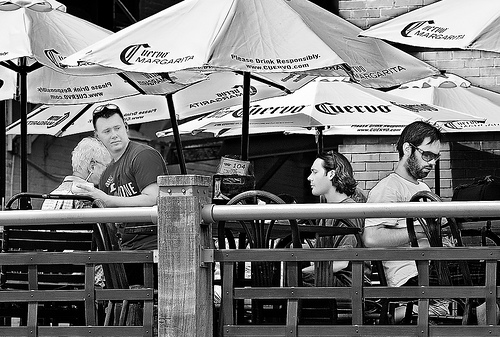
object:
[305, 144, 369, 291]
person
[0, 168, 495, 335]
patio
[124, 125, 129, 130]
earbuds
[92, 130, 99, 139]
ears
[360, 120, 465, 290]
man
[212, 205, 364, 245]
table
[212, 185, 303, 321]
chair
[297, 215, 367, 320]
chair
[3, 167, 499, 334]
fence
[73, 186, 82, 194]
glass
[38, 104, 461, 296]
people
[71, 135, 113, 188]
head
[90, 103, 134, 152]
head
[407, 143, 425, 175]
beard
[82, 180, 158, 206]
arm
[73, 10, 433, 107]
umbrella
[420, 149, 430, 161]
eye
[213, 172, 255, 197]
box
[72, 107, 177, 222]
person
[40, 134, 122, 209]
person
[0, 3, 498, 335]
cafe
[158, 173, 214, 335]
pole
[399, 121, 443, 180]
head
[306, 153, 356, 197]
head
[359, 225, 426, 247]
arm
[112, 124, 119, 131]
eye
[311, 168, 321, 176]
eye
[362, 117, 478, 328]
person